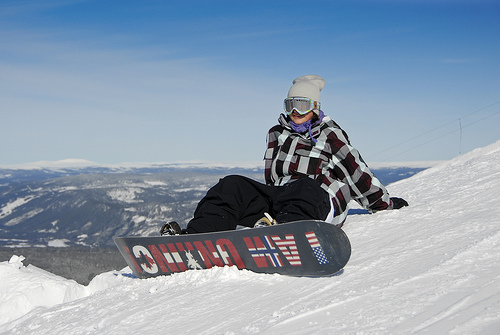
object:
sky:
[0, 0, 499, 164]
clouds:
[75, 91, 189, 133]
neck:
[283, 117, 322, 131]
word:
[241, 233, 302, 268]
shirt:
[242, 111, 413, 225]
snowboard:
[112, 219, 352, 279]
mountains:
[0, 156, 135, 175]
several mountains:
[0, 157, 265, 248]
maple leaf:
[137, 252, 155, 272]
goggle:
[283, 96, 321, 115]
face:
[287, 97, 313, 125]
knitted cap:
[286, 74, 326, 117]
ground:
[0, 137, 499, 334]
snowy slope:
[0, 138, 500, 335]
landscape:
[0, 1, 499, 334]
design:
[304, 230, 330, 266]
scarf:
[286, 109, 326, 143]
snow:
[0, 139, 498, 334]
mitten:
[389, 197, 409, 211]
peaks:
[52, 157, 97, 165]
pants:
[168, 167, 333, 245]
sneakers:
[159, 220, 182, 236]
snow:
[0, 159, 450, 248]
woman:
[159, 73, 410, 240]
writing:
[121, 230, 329, 274]